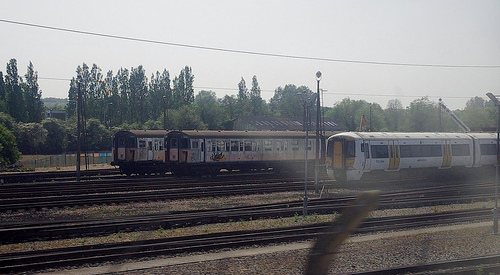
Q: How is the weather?
A: It is overcast.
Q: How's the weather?
A: It is overcast.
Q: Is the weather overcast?
A: Yes, it is overcast.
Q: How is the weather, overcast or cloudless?
A: It is overcast.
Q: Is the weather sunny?
A: No, it is overcast.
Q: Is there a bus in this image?
A: No, there are no buses.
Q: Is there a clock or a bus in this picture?
A: No, there are no buses or clocks.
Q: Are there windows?
A: Yes, there are windows.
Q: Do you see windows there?
A: Yes, there are windows.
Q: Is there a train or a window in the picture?
A: Yes, there are windows.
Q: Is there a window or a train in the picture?
A: Yes, there are windows.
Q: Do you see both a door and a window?
A: Yes, there are both a window and a door.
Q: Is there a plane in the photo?
A: No, there are no airplanes.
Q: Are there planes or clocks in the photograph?
A: No, there are no planes or clocks.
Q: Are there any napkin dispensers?
A: No, there are no napkin dispensers.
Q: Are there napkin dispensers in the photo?
A: No, there are no napkin dispensers.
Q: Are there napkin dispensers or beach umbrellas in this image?
A: No, there are no napkin dispensers or beach umbrellas.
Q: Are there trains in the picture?
A: Yes, there is a train.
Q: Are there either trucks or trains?
A: Yes, there is a train.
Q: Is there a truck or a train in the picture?
A: Yes, there is a train.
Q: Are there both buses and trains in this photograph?
A: No, there is a train but no buses.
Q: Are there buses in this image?
A: No, there are no buses.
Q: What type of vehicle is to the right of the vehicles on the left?
A: The vehicle is a train.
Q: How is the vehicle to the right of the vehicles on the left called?
A: The vehicle is a train.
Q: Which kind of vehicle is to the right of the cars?
A: The vehicle is a train.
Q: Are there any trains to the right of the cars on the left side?
A: Yes, there is a train to the right of the cars.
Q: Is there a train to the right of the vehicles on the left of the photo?
A: Yes, there is a train to the right of the cars.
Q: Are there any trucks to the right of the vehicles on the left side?
A: No, there is a train to the right of the cars.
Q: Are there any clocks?
A: No, there are no clocks.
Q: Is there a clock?
A: No, there are no clocks.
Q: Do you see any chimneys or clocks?
A: No, there are no clocks or chimneys.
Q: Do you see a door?
A: Yes, there are doors.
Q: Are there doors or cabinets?
A: Yes, there are doors.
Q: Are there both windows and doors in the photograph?
A: Yes, there are both doors and windows.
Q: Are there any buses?
A: No, there are no buses.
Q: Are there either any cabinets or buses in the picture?
A: No, there are no buses or cabinets.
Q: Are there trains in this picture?
A: Yes, there are trains.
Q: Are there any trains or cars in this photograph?
A: Yes, there are trains.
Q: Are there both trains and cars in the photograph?
A: Yes, there are both trains and cars.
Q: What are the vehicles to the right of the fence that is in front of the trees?
A: The vehicles are trains.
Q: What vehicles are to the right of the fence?
A: The vehicles are trains.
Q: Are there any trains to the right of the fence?
A: Yes, there are trains to the right of the fence.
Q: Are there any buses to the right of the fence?
A: No, there are trains to the right of the fence.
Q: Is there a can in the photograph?
A: No, there are no cans.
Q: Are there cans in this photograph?
A: No, there are no cans.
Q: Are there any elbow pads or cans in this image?
A: No, there are no cans or elbow pads.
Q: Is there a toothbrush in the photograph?
A: No, there are no toothbrushes.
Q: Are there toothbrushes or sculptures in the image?
A: No, there are no toothbrushes or sculptures.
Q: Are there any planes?
A: No, there are no planes.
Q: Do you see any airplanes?
A: No, there are no airplanes.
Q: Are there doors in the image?
A: Yes, there is a door.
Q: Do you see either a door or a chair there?
A: Yes, there is a door.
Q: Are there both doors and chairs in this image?
A: No, there is a door but no chairs.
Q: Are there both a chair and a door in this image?
A: No, there is a door but no chairs.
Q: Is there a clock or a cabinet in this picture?
A: No, there are no clocks or cabinets.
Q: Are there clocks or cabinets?
A: No, there are no clocks or cabinets.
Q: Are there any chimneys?
A: No, there are no chimneys.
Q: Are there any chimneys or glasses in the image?
A: No, there are no chimneys or glasses.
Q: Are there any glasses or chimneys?
A: No, there are no chimneys or glasses.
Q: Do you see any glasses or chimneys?
A: No, there are no chimneys or glasses.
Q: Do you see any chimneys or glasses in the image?
A: No, there are no chimneys or glasses.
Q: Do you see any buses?
A: No, there are no buses.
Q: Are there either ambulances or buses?
A: No, there are no buses or ambulances.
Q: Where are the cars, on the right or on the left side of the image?
A: The cars are on the left of the image.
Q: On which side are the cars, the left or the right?
A: The cars are on the left of the image.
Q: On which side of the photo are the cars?
A: The cars are on the left of the image.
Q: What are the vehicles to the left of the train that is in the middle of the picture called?
A: The vehicles are cars.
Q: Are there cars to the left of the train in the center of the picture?
A: Yes, there are cars to the left of the train.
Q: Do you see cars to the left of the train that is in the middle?
A: Yes, there are cars to the left of the train.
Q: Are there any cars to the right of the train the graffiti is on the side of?
A: No, the cars are to the left of the train.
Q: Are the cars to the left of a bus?
A: No, the cars are to the left of the train.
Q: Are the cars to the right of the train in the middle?
A: No, the cars are to the left of the train.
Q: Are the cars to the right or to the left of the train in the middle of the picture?
A: The cars are to the left of the train.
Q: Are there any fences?
A: Yes, there is a fence.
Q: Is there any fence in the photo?
A: Yes, there is a fence.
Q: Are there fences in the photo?
A: Yes, there is a fence.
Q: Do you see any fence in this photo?
A: Yes, there is a fence.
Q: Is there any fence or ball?
A: Yes, there is a fence.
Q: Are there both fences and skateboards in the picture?
A: No, there is a fence but no skateboards.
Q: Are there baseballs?
A: No, there are no baseballs.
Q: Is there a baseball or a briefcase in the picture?
A: No, there are no baseballs or briefcases.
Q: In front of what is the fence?
A: The fence is in front of the trees.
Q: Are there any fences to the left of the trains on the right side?
A: Yes, there is a fence to the left of the trains.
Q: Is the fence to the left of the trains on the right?
A: Yes, the fence is to the left of the trains.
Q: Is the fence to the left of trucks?
A: No, the fence is to the left of the trains.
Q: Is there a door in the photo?
A: Yes, there is a door.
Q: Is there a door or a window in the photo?
A: Yes, there is a door.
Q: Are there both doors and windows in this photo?
A: Yes, there are both a door and a window.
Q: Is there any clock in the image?
A: No, there are no clocks.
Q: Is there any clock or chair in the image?
A: No, there are no clocks or chairs.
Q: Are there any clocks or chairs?
A: No, there are no clocks or chairs.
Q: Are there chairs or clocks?
A: No, there are no clocks or chairs.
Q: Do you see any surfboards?
A: No, there are no surfboards.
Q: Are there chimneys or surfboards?
A: No, there are no surfboards or chimneys.